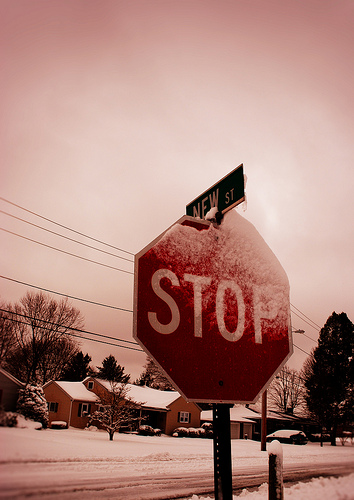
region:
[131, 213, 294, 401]
sign is red and white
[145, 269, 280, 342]
the sign says STOP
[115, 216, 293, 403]
the sign is octagon shaped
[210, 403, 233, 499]
green metal pole holding sign up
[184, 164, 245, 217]
green street sign on stop sign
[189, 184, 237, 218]
street sign says NEW ST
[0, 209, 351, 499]
snow covered objects in photo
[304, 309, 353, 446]
green pine tree by car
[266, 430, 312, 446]
car covered in snow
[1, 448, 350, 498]
street has several tracks in it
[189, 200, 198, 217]
white letter on sign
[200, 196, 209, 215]
white letter on sign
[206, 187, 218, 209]
white letter on sign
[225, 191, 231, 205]
white letter on sign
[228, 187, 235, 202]
white letter on sign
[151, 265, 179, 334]
white letter on sign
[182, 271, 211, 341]
white letter on sign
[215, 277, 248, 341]
white letter on sign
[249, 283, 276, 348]
white letter on sign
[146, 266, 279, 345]
white letters on sign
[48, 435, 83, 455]
Ground is covered in snow.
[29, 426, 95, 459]
Snow on ground is white.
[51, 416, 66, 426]
Snow on top of bush.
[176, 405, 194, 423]
Window on front of house.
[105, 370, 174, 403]
Snow covering roof of house.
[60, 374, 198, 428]
House is tan in color.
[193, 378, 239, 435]
Red sign attached to pole.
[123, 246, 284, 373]
White letters on red sign.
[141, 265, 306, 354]
Sign says stop in large letters.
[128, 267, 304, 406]
Sign has 8 sides.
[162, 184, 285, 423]
red and white sign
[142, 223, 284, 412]
white letters on sign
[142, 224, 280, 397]
stop sign is octagonal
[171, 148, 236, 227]
green and white sign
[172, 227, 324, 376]
white snow on stop sign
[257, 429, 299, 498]
small post near stop sign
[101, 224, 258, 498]
stop sign on dark post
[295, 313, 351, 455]
tall and green tree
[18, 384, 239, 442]
brown house across road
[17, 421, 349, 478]
snow in front of house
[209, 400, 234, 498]
a pole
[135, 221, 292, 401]
a red stop sign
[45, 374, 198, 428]
a brick house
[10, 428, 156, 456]
snow on the ground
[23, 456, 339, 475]
tracks in the snow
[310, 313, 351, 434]
a tall pine tree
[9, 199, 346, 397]
telephone pole wires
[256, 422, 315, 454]
a car in the driveway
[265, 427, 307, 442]
a car with snow on top of it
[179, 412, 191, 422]
a window of the house